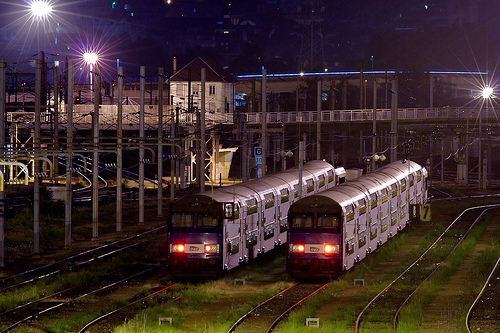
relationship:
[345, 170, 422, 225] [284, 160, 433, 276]
many windows on train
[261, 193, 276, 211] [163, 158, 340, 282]
window on train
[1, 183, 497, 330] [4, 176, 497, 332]
train tracks on ground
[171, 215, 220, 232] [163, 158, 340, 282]
front windows on train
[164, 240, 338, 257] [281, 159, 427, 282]
lights on train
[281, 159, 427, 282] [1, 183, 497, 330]
train are on train tracks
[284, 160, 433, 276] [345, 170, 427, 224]
train has many windows